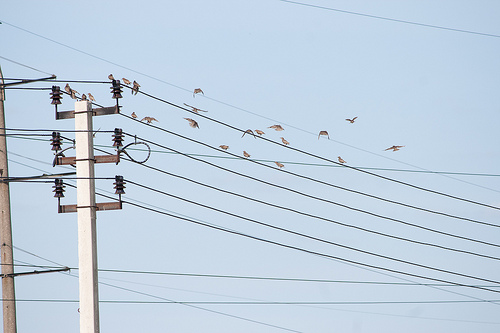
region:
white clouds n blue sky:
[220, 35, 268, 92]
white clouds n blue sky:
[351, 113, 462, 188]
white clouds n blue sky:
[364, 243, 391, 271]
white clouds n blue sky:
[235, 232, 299, 283]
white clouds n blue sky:
[167, 152, 219, 226]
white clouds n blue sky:
[227, 43, 321, 113]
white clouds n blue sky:
[152, 29, 240, 110]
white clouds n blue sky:
[321, 203, 389, 270]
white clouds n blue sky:
[411, 119, 459, 201]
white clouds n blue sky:
[280, 41, 332, 132]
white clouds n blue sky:
[51, 16, 122, 73]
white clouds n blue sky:
[407, 43, 464, 98]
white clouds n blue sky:
[338, 219, 393, 296]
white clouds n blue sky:
[207, 209, 265, 249]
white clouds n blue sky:
[265, 66, 357, 151]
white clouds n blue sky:
[194, 53, 279, 143]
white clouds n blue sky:
[177, 25, 231, 83]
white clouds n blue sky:
[137, 185, 202, 246]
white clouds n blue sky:
[267, 181, 348, 268]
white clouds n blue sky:
[350, 153, 412, 234]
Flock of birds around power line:
[50, 71, 408, 171]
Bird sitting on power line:
[278, 135, 290, 147]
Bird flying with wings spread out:
[382, 143, 405, 154]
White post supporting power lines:
[72, 98, 102, 330]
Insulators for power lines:
[51, 78, 125, 213]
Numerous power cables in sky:
[1, 20, 496, 302]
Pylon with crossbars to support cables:
[0, 68, 72, 331]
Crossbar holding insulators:
[53, 104, 120, 119]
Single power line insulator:
[113, 173, 125, 195]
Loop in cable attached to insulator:
[121, 139, 151, 164]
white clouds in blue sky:
[350, 21, 406, 55]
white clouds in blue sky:
[354, 92, 416, 134]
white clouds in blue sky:
[257, 154, 321, 214]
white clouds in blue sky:
[242, 19, 308, 106]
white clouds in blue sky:
[163, 179, 220, 232]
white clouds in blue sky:
[77, 12, 124, 35]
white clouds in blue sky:
[223, 49, 287, 115]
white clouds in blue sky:
[185, 124, 266, 201]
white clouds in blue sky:
[257, 0, 312, 79]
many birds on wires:
[118, 62, 445, 202]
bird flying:
[383, 135, 407, 159]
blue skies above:
[0, 2, 498, 320]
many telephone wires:
[0, 32, 497, 332]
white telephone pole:
[38, 74, 131, 331]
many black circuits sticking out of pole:
[105, 75, 154, 202]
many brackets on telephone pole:
[44, 75, 128, 216]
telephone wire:
[0, 242, 495, 279]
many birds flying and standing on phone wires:
[312, 88, 400, 161]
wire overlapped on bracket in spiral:
[55, 132, 161, 164]